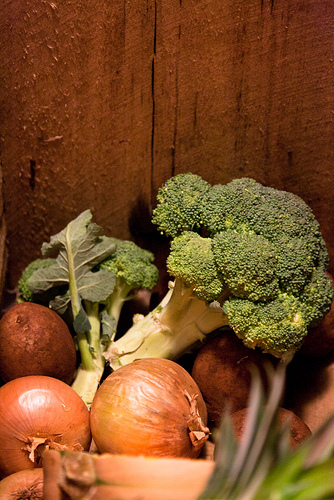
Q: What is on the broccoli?
A: A leaf is on the broccoli.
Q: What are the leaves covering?
A: The leaves are covering a potato.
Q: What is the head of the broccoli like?
A: The head of broccoli is leafy.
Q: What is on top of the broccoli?
A: Onions are on top of the broccoli?.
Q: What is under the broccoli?
A: A potato is under the broccoli.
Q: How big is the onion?
A: The onion is small.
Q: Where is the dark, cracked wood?
A: Behind the vegetables.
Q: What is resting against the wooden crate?
A: Vegetables.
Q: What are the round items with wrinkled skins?
A: Onions.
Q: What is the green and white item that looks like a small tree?
A: A big broccoli floret.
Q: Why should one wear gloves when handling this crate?
A: To avoid getting splinters.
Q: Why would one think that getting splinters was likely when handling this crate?
A: Because the wood is rough, cracked and peeling.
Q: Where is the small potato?
A: Beside the large leaf of a slender broccoli floret.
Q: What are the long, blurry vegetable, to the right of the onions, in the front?
A: Scallions.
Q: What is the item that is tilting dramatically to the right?
A: The stalk of broccoli.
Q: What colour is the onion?
A: Brown.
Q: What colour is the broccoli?
A: Green.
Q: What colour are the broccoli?
A: Green.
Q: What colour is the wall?
A: Brown.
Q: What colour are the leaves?
A: Green.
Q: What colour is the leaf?
A: Green.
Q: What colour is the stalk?
A: White.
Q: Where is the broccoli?
A: On the veggies.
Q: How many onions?
A: 2.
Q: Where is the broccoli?
A: On the top.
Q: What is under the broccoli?
A: Onions.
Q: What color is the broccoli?
A: Green.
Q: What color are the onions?
A: Yellow.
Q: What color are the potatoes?
A: Brown.